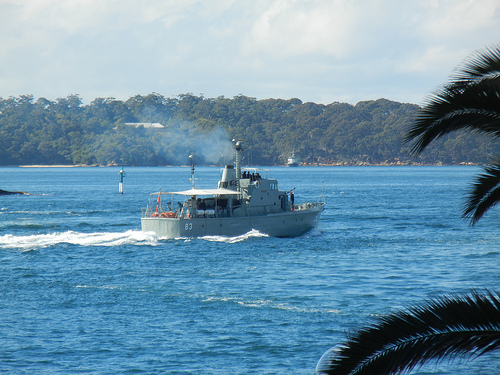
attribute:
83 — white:
[180, 221, 198, 236]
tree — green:
[314, 296, 496, 373]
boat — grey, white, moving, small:
[140, 216, 328, 237]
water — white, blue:
[84, 277, 207, 300]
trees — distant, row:
[215, 116, 335, 145]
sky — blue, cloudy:
[371, 35, 398, 54]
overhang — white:
[188, 186, 212, 197]